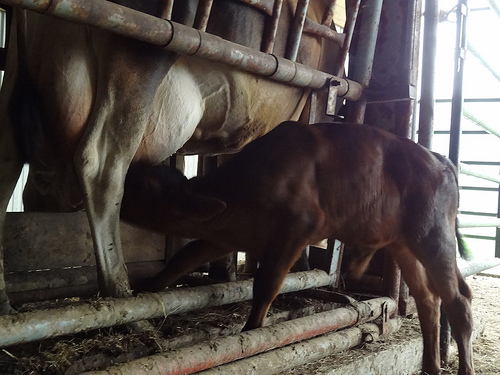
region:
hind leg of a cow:
[64, 38, 178, 309]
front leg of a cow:
[227, 208, 314, 348]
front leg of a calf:
[145, 227, 246, 294]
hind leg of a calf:
[406, 210, 483, 370]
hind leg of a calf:
[390, 242, 443, 374]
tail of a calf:
[435, 150, 473, 263]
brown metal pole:
[446, 3, 479, 177]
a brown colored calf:
[114, 113, 479, 373]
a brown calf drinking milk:
[112, 103, 491, 373]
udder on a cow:
[129, 76, 214, 170]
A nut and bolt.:
[321, 76, 343, 90]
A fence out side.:
[467, 99, 499, 256]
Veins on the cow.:
[195, 81, 240, 139]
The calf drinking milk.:
[111, 159, 209, 259]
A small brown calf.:
[146, 111, 481, 369]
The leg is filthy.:
[71, 164, 138, 302]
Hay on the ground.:
[476, 295, 499, 373]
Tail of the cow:
[6, 2, 54, 169]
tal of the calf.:
[448, 182, 471, 262]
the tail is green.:
[458, 230, 476, 259]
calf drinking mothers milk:
[124, 118, 484, 370]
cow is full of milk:
[101, 91, 218, 233]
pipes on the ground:
[64, 276, 417, 366]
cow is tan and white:
[25, 21, 331, 255]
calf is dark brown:
[155, 134, 494, 359]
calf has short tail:
[429, 147, 482, 284]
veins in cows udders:
[136, 98, 170, 153]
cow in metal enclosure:
[136, 6, 372, 111]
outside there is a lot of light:
[434, 18, 496, 200]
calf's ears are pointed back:
[144, 173, 226, 243]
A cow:
[179, 121, 436, 339]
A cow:
[226, 140, 337, 353]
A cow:
[196, 168, 281, 330]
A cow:
[191, 104, 328, 297]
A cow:
[260, 162, 392, 359]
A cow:
[222, 69, 373, 326]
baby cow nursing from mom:
[32, 141, 198, 261]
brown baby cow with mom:
[161, 128, 477, 285]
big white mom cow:
[18, 10, 210, 188]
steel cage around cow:
[47, 11, 404, 112]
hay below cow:
[18, 293, 133, 360]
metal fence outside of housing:
[436, 87, 478, 172]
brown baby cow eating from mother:
[21, 81, 193, 273]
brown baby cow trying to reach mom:
[79, 128, 464, 315]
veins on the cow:
[198, 68, 243, 156]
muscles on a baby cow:
[387, 147, 478, 339]